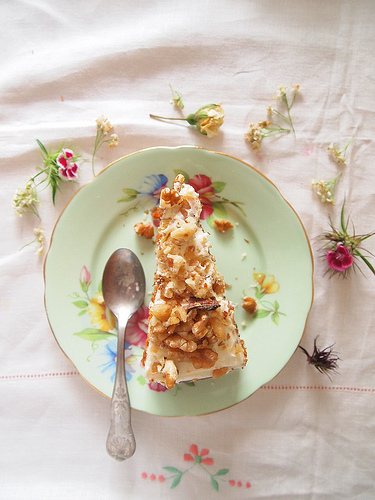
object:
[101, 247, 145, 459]
spoon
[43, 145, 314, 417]
dish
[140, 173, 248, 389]
pastry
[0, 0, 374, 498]
tablecloth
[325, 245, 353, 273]
flower